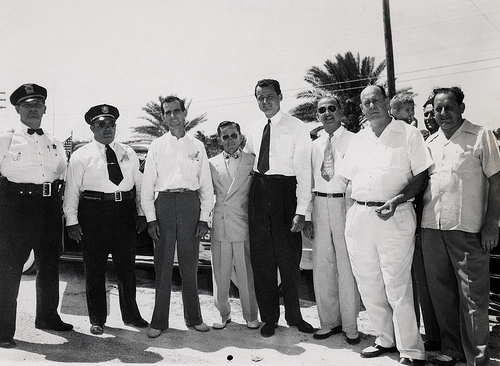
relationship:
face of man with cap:
[91, 118, 117, 140] [85, 104, 124, 114]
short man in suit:
[203, 102, 266, 340] [199, 152, 255, 253]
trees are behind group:
[135, 43, 391, 144] [0, 69, 498, 362]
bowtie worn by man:
[26, 125, 53, 137] [7, 69, 75, 354]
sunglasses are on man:
[91, 118, 118, 129] [59, 82, 160, 334]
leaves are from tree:
[306, 68, 332, 89] [285, 46, 393, 129]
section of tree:
[341, 49, 360, 100] [285, 46, 393, 129]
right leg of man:
[338, 198, 392, 353] [340, 78, 429, 366]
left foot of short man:
[243, 315, 263, 331] [203, 115, 264, 330]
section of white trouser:
[348, 219, 382, 296] [340, 203, 430, 360]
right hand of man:
[142, 220, 168, 240] [135, 84, 222, 348]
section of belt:
[312, 189, 343, 198] [311, 189, 349, 201]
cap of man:
[85, 104, 124, 114] [59, 82, 160, 334]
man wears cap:
[59, 82, 160, 334] [85, 104, 124, 114]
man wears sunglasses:
[135, 84, 222, 348] [158, 108, 191, 119]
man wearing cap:
[7, 69, 75, 354] [13, 87, 47, 100]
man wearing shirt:
[340, 78, 429, 366] [327, 117, 436, 211]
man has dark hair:
[135, 84, 222, 348] [160, 95, 187, 107]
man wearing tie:
[59, 82, 160, 334] [100, 142, 130, 185]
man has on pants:
[59, 82, 160, 334] [76, 188, 147, 327]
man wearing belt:
[296, 90, 370, 341] [311, 189, 349, 201]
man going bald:
[340, 78, 429, 366] [356, 84, 387, 99]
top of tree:
[296, 46, 414, 74] [285, 46, 393, 129]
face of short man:
[217, 125, 242, 149] [203, 102, 266, 340]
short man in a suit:
[203, 102, 266, 340] [199, 152, 255, 253]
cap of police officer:
[85, 104, 124, 114] [58, 81, 156, 339]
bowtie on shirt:
[26, 125, 53, 137] [2, 117, 76, 191]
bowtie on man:
[26, 125, 53, 137] [7, 69, 75, 354]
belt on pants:
[311, 189, 349, 201] [308, 186, 364, 334]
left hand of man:
[194, 218, 217, 244] [135, 84, 222, 348]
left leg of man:
[174, 197, 212, 329] [135, 84, 222, 348]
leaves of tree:
[306, 68, 332, 89] [285, 46, 393, 129]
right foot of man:
[137, 319, 174, 341] [135, 84, 222, 348]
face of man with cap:
[23, 96, 44, 119] [13, 87, 47, 100]